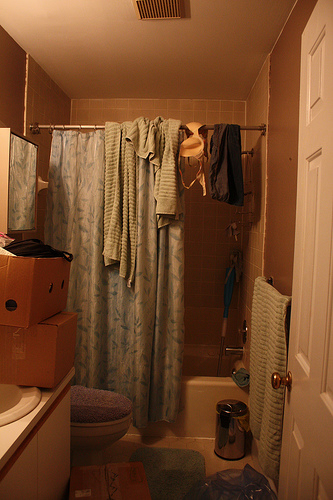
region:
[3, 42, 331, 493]
a restroom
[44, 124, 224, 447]
a shower curtain that is partially pulled back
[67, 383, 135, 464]
a toilet with a toilet seat cover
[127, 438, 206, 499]
a mat on the ground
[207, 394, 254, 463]
a waste paper bin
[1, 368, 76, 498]
a sink and cabinets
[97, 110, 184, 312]
towels hung over a shower curtain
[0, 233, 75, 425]
boxes beside a sink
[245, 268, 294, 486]
towel hanging on rack near doorknob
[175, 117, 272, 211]
undergarments hanging from shower rod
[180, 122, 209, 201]
gold bra hanging on shower rod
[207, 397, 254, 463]
shiny silver trash can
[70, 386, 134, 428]
fuzzy purple toilet seat cover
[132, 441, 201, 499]
light blue bath mat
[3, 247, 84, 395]
two cardboard boxes sitting on bathroom sink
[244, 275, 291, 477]
textured green towel hanging on drying rack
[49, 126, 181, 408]
long, blue patterned showered curtain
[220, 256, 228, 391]
blue cleaning tool propped up in shower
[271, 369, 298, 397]
gold doorknob on a white door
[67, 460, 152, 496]
brown cardboard box with scribbles on it sitting on the bathroom floor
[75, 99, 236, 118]
brown tiled bath wall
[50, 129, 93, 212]
pattern of shower curtain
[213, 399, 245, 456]
small metal bathroom trash can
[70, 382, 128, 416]
fabric toilet seat cover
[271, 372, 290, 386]
the bathroom door knob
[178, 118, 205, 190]
beige bra hanging up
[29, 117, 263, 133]
the metal shower curtain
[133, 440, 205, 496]
the small bathroom rug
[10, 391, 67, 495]
two bathroom cabinet doors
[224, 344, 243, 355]
the bath tub faucet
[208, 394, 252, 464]
tiny silver trash can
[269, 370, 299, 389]
gold doorknob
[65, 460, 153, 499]
brown cardboard box with scribbles on it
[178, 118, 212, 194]
gold bra hanging over the shower rod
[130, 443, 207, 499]
blue rectangular bath mat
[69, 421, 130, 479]
white toilet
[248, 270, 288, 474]
green towel hanging on drying rack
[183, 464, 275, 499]
blue trash bag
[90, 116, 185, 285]
three green towels hanging over shower rod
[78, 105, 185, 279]
towels hanging over shower rod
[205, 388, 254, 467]
silver trash can by tub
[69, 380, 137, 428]
lavender lid cover on toilet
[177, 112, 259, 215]
underwear hanging on shower rod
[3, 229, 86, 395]
two boxes on counter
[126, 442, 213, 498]
green bath rug on floor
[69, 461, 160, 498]
box on floor in bathroom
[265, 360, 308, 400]
gold door knob on door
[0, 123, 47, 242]
medicine cabinet on wall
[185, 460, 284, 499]
plastic bag on bathroom floor